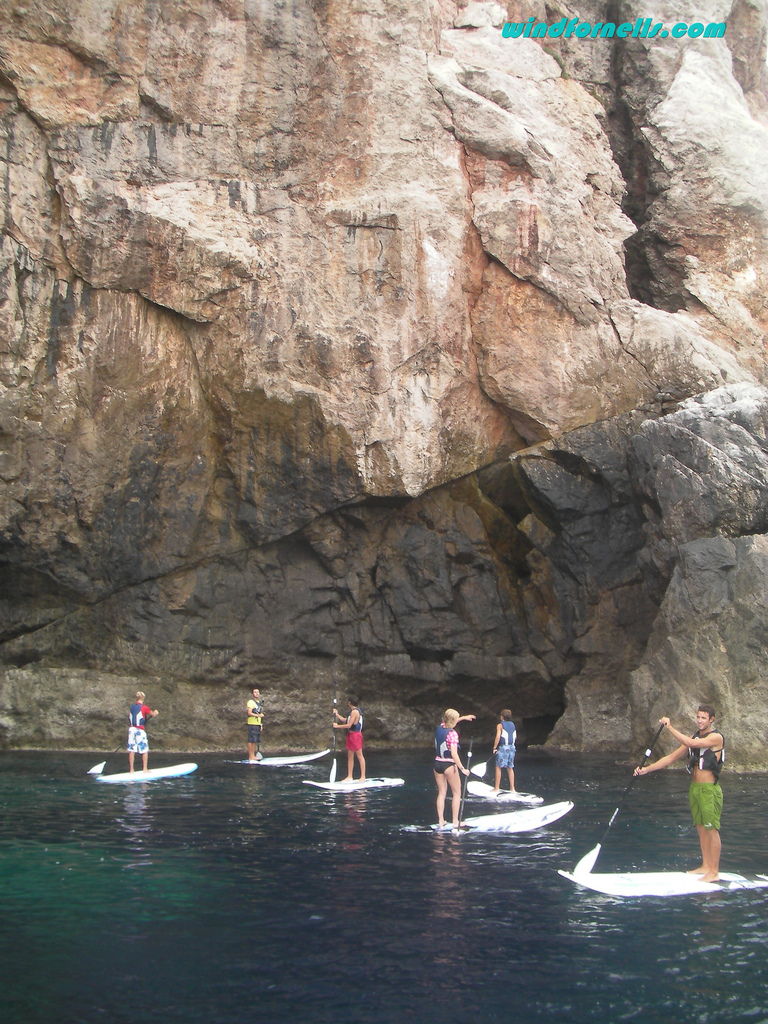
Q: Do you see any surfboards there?
A: Yes, there is a surfboard.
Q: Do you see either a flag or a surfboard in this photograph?
A: Yes, there is a surfboard.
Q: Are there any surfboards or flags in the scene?
A: Yes, there is a surfboard.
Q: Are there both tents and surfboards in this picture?
A: No, there is a surfboard but no tents.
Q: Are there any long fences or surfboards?
A: Yes, there is a long surfboard.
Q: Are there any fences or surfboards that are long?
A: Yes, the surfboard is long.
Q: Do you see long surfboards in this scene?
A: Yes, there is a long surfboard.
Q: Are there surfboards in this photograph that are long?
A: Yes, there is a surfboard that is long.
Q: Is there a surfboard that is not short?
A: Yes, there is a long surfboard.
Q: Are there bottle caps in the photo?
A: No, there are no bottle caps.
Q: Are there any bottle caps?
A: No, there are no bottle caps.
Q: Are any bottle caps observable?
A: No, there are no bottle caps.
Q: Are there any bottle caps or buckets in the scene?
A: No, there are no bottle caps or buckets.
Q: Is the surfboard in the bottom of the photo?
A: Yes, the surfboard is in the bottom of the image.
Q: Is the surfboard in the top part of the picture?
A: No, the surfboard is in the bottom of the image.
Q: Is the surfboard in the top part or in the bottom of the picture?
A: The surfboard is in the bottom of the image.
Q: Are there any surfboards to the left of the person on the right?
A: Yes, there is a surfboard to the left of the person.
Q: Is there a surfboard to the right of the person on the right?
A: No, the surfboard is to the left of the person.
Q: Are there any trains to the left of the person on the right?
A: No, there is a surfboard to the left of the person.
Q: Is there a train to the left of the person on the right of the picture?
A: No, there is a surfboard to the left of the person.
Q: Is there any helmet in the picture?
A: No, there are no helmets.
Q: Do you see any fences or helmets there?
A: No, there are no helmets or fences.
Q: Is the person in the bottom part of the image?
A: Yes, the person is in the bottom of the image.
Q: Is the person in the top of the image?
A: No, the person is in the bottom of the image.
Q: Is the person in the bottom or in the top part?
A: The person is in the bottom of the image.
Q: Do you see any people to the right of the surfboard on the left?
A: Yes, there is a person to the right of the surf board.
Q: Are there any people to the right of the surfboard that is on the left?
A: Yes, there is a person to the right of the surf board.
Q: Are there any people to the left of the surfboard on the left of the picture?
A: No, the person is to the right of the surfboard.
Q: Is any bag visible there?
A: No, there are no bags.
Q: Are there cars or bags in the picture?
A: No, there are no bags or cars.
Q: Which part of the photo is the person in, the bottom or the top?
A: The person is in the bottom of the image.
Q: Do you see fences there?
A: No, there are no fences.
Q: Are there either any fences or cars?
A: No, there are no fences or cars.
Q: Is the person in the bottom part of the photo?
A: Yes, the person is in the bottom of the image.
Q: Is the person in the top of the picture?
A: No, the person is in the bottom of the image.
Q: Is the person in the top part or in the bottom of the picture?
A: The person is in the bottom of the image.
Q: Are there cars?
A: No, there are no cars.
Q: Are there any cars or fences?
A: No, there are no cars or fences.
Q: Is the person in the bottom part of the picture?
A: Yes, the person is in the bottom of the image.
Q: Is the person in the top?
A: No, the person is in the bottom of the image.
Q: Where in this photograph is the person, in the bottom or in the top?
A: The person is in the bottom of the image.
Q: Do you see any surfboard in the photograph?
A: Yes, there is a surfboard.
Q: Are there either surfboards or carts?
A: Yes, there is a surfboard.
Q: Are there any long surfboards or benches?
A: Yes, there is a long surfboard.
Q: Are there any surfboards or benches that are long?
A: Yes, the surfboard is long.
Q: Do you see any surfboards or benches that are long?
A: Yes, the surfboard is long.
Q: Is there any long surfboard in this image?
A: Yes, there is a long surfboard.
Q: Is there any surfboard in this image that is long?
A: Yes, there is a surfboard that is long.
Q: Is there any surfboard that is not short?
A: Yes, there is a long surfboard.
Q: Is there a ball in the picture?
A: No, there are no balls.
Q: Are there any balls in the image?
A: No, there are no balls.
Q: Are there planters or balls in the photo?
A: No, there are no balls or planters.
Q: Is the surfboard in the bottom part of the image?
A: Yes, the surfboard is in the bottom of the image.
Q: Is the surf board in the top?
A: No, the surf board is in the bottom of the image.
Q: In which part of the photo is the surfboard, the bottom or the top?
A: The surfboard is in the bottom of the image.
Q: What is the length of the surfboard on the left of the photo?
A: The surfboard is long.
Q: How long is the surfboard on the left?
A: The surfboard is long.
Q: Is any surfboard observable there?
A: Yes, there is a surfboard.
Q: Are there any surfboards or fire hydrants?
A: Yes, there is a surfboard.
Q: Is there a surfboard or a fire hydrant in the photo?
A: Yes, there is a surfboard.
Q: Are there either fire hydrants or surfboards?
A: Yes, there is a surfboard.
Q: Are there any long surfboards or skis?
A: Yes, there is a long surfboard.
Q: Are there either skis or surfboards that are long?
A: Yes, the surfboard is long.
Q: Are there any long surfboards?
A: Yes, there is a long surfboard.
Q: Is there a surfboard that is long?
A: Yes, there is a surfboard that is long.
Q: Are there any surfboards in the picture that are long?
A: Yes, there is a surfboard that is long.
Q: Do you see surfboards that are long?
A: Yes, there is a surfboard that is long.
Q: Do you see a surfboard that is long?
A: Yes, there is a surfboard that is long.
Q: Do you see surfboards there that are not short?
A: Yes, there is a long surfboard.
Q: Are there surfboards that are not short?
A: Yes, there is a long surfboard.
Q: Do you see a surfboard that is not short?
A: Yes, there is a long surfboard.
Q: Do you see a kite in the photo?
A: No, there are no kites.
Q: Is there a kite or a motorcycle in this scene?
A: No, there are no kites or motorcycles.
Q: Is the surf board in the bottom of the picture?
A: Yes, the surf board is in the bottom of the image.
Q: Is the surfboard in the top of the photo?
A: No, the surfboard is in the bottom of the image.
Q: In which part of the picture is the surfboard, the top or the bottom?
A: The surfboard is in the bottom of the image.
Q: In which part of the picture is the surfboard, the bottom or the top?
A: The surfboard is in the bottom of the image.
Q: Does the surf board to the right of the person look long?
A: Yes, the surfboard is long.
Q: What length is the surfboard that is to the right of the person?
A: The surfboard is long.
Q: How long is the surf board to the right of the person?
A: The surfboard is long.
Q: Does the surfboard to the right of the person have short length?
A: No, the surfboard is long.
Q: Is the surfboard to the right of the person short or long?
A: The surfboard is long.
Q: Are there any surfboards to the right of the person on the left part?
A: Yes, there is a surfboard to the right of the person.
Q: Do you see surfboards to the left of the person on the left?
A: No, the surfboard is to the right of the person.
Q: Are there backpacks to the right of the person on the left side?
A: No, there is a surfboard to the right of the person.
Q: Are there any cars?
A: No, there are no cars.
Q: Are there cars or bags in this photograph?
A: No, there are no cars or bags.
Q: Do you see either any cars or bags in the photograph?
A: No, there are no cars or bags.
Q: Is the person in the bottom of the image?
A: Yes, the person is in the bottom of the image.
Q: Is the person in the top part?
A: No, the person is in the bottom of the image.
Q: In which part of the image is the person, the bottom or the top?
A: The person is in the bottom of the image.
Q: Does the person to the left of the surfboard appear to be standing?
A: Yes, the person is standing.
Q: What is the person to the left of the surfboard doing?
A: The person is standing.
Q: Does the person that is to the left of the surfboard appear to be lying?
A: No, the person is standing.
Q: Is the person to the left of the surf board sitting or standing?
A: The person is standing.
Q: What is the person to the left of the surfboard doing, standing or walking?
A: The person is standing.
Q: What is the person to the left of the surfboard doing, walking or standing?
A: The person is standing.